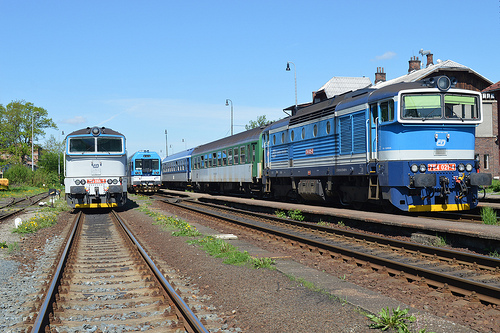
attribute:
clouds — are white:
[358, 39, 413, 65]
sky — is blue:
[2, 0, 497, 188]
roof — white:
[310, 73, 375, 103]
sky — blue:
[0, 1, 497, 158]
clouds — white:
[47, 96, 295, 158]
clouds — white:
[372, 50, 394, 63]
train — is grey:
[47, 110, 149, 229]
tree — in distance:
[0, 100, 57, 165]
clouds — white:
[119, 62, 231, 137]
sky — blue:
[27, 17, 231, 101]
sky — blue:
[130, 44, 270, 106]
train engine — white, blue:
[265, 71, 482, 221]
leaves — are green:
[22, 104, 24, 115]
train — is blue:
[164, 84, 477, 212]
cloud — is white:
[142, 97, 217, 124]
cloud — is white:
[139, 98, 209, 121]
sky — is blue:
[4, 4, 494, 48]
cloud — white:
[118, 96, 233, 123]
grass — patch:
[214, 242, 286, 271]